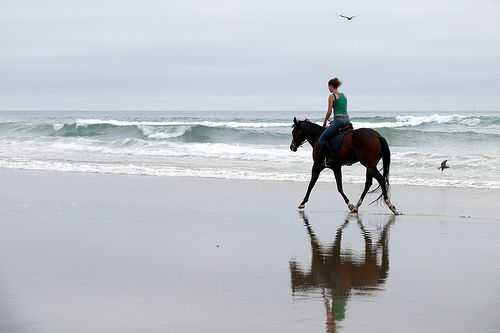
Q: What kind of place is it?
A: It is a beach.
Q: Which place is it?
A: It is a beach.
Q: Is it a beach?
A: Yes, it is a beach.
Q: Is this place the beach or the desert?
A: It is the beach.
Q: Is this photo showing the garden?
A: No, the picture is showing the beach.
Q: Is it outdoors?
A: Yes, it is outdoors.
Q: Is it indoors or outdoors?
A: It is outdoors.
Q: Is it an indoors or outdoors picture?
A: It is outdoors.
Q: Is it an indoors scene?
A: No, it is outdoors.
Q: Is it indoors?
A: No, it is outdoors.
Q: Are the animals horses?
A: No, they are horses and birds.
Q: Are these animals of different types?
A: Yes, they are horses and birds.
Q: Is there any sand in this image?
A: Yes, there is sand.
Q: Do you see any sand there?
A: Yes, there is sand.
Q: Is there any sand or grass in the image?
A: Yes, there is sand.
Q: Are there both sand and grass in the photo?
A: No, there is sand but no grass.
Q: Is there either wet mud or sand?
A: Yes, there is wet sand.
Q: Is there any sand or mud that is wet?
A: Yes, the sand is wet.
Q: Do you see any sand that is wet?
A: Yes, there is wet sand.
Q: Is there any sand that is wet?
A: Yes, there is sand that is wet.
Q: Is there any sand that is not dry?
A: Yes, there is wet sand.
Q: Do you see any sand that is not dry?
A: Yes, there is wet sand.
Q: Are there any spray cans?
A: No, there are no spray cans.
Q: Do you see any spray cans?
A: No, there are no spray cans.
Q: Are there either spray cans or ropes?
A: No, there are no spray cans or ropes.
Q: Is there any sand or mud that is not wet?
A: No, there is sand but it is wet.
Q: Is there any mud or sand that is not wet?
A: No, there is sand but it is wet.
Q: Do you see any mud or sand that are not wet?
A: No, there is sand but it is wet.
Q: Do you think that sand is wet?
A: Yes, the sand is wet.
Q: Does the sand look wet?
A: Yes, the sand is wet.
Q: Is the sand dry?
A: No, the sand is wet.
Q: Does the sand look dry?
A: No, the sand is wet.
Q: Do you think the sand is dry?
A: No, the sand is wet.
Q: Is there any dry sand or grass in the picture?
A: No, there is sand but it is wet.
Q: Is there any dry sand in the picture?
A: No, there is sand but it is wet.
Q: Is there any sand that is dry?
A: No, there is sand but it is wet.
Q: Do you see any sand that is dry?
A: No, there is sand but it is wet.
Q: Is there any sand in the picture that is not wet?
A: No, there is sand but it is wet.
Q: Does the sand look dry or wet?
A: The sand is wet.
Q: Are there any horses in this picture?
A: Yes, there is a horse.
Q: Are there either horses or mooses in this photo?
A: Yes, there is a horse.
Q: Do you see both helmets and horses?
A: No, there is a horse but no helmets.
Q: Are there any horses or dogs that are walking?
A: Yes, the horse is walking.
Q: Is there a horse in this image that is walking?
A: Yes, there is a horse that is walking.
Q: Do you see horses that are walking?
A: Yes, there is a horse that is walking.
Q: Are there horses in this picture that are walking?
A: Yes, there is a horse that is walking.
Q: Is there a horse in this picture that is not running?
A: Yes, there is a horse that is walking.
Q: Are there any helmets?
A: No, there are no helmets.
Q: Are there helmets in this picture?
A: No, there are no helmets.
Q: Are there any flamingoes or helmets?
A: No, there are no helmets or flamingoes.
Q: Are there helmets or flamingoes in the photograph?
A: No, there are no helmets or flamingoes.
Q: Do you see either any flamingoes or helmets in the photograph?
A: No, there are no helmets or flamingoes.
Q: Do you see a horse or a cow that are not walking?
A: No, there is a horse but it is walking.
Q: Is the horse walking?
A: Yes, the horse is walking.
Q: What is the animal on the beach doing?
A: The horse is walking.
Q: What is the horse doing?
A: The horse is walking.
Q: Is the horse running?
A: No, the horse is walking.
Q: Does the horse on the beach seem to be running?
A: No, the horse is walking.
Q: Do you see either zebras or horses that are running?
A: No, there is a horse but it is walking.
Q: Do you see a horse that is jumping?
A: No, there is a horse but it is walking.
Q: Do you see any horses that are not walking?
A: No, there is a horse but it is walking.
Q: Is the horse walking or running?
A: The horse is walking.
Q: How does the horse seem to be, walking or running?
A: The horse is walking.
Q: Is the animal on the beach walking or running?
A: The horse is walking.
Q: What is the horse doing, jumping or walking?
A: The horse is walking.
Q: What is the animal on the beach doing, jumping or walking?
A: The horse is walking.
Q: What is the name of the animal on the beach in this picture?
A: The animal is a horse.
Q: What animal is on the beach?
A: The animal is a horse.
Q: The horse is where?
A: The horse is on the beach.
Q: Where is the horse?
A: The horse is on the beach.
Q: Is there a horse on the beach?
A: Yes, there is a horse on the beach.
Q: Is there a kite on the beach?
A: No, there is a horse on the beach.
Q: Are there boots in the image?
A: Yes, there are boots.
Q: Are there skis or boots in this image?
A: Yes, there are boots.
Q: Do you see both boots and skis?
A: No, there are boots but no skis.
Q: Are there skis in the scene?
A: No, there are no skis.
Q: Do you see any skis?
A: No, there are no skis.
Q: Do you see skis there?
A: No, there are no skis.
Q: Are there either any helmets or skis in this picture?
A: No, there are no skis or helmets.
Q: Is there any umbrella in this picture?
A: No, there are no umbrellas.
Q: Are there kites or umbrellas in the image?
A: No, there are no umbrellas or kites.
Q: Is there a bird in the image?
A: Yes, there is a bird.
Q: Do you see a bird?
A: Yes, there is a bird.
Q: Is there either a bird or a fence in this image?
A: Yes, there is a bird.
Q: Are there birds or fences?
A: Yes, there is a bird.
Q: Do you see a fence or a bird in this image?
A: Yes, there is a bird.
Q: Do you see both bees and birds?
A: No, there is a bird but no bees.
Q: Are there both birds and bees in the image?
A: No, there is a bird but no bees.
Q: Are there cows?
A: No, there are no cows.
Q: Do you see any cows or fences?
A: No, there are no cows or fences.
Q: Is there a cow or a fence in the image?
A: No, there are no cows or fences.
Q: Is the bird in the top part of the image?
A: Yes, the bird is in the top of the image.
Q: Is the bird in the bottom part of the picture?
A: No, the bird is in the top of the image.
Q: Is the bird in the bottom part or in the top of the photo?
A: The bird is in the top of the image.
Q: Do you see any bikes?
A: No, there are no bikes.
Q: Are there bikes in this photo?
A: No, there are no bikes.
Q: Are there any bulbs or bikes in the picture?
A: No, there are no bikes or bulbs.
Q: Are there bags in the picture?
A: No, there are no bags.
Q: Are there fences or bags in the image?
A: No, there are no bags or fences.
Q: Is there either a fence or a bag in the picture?
A: No, there are no bags or fences.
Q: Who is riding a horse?
A: The girl is riding a horse.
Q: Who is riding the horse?
A: The girl is riding a horse.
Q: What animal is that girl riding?
A: The girl is riding a horse.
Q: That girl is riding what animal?
A: The girl is riding a horse.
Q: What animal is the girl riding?
A: The girl is riding a horse.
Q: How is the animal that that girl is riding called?
A: The animal is a horse.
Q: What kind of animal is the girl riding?
A: The girl is riding a horse.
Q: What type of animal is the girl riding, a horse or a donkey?
A: The girl is riding a horse.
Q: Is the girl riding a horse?
A: Yes, the girl is riding a horse.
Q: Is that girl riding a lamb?
A: No, the girl is riding a horse.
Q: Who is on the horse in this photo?
A: The girl is on the horse.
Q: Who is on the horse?
A: The girl is on the horse.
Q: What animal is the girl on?
A: The girl is on the horse.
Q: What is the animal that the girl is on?
A: The animal is a horse.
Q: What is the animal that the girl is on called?
A: The animal is a horse.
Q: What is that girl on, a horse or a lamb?
A: The girl is on a horse.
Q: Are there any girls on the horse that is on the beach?
A: Yes, there is a girl on the horse.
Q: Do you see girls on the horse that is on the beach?
A: Yes, there is a girl on the horse.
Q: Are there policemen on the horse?
A: No, there is a girl on the horse.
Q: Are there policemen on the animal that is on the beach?
A: No, there is a girl on the horse.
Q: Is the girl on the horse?
A: Yes, the girl is on the horse.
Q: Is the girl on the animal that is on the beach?
A: Yes, the girl is on the horse.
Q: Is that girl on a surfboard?
A: No, the girl is on the horse.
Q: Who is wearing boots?
A: The girl is wearing boots.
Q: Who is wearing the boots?
A: The girl is wearing boots.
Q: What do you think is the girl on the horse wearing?
A: The girl is wearing boots.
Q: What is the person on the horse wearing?
A: The girl is wearing boots.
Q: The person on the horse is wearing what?
A: The girl is wearing boots.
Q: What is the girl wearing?
A: The girl is wearing boots.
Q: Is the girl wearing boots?
A: Yes, the girl is wearing boots.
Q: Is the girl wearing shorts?
A: No, the girl is wearing boots.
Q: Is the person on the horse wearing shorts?
A: No, the girl is wearing boots.